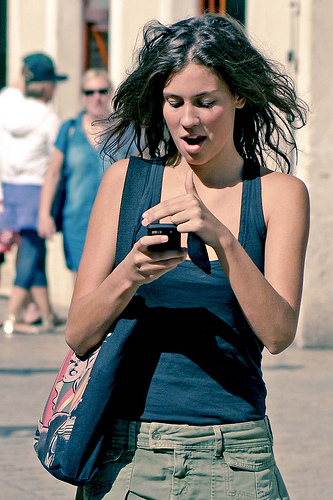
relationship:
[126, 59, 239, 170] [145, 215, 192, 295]
girl with phone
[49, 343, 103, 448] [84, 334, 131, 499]
drawings on bag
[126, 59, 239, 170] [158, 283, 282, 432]
girl wearing top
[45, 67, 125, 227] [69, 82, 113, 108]
woman with sunglasses